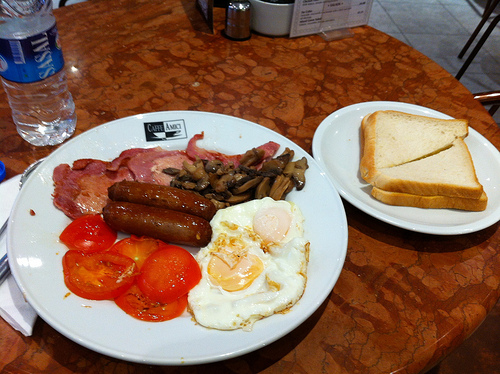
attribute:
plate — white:
[7, 110, 347, 364]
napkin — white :
[3, 285, 28, 320]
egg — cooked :
[191, 196, 313, 328]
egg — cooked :
[187, 233, 307, 328]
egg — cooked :
[208, 197, 308, 249]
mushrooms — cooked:
[161, 143, 312, 204]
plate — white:
[313, 97, 498, 236]